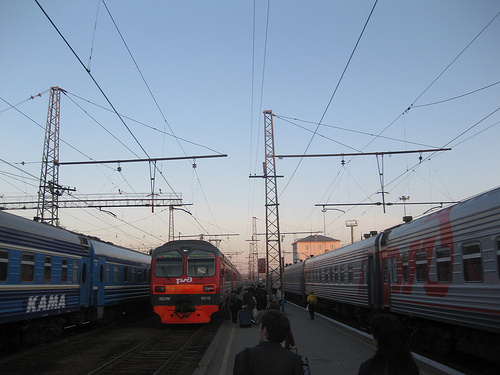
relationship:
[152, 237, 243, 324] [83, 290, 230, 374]
train on rail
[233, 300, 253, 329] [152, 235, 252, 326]
people waiting to board train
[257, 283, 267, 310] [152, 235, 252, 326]
people waiting to board train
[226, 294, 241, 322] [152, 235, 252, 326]
people waiting to board train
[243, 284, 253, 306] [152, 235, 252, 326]
people waiting to board train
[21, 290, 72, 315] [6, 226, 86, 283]
kama written on side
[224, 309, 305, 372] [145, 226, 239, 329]
man looking at train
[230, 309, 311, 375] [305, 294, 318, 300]
man wearing shirt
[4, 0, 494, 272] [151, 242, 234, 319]
sky above train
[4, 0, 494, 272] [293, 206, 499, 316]
sky above train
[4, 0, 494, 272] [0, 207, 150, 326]
sky above train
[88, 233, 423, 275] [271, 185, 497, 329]
sunset above train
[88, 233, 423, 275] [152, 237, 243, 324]
sunset above train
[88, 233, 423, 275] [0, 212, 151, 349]
sunset above train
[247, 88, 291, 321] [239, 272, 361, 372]
tower in walkway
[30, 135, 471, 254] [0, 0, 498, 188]
clouds in sky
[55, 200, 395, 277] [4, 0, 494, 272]
clouds in sky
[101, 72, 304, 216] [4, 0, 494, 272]
white clouds in sky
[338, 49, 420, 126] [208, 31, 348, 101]
white clouds in blue sky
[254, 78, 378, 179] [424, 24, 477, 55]
clouds in sky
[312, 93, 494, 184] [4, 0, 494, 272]
clouds in sky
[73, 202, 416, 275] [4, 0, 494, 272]
clouds in sky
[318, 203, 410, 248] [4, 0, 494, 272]
cloud in sky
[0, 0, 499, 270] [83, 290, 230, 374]
electric cables over rail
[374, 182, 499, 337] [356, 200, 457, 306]
passenger car with red letters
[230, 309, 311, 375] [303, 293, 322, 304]
man in a shirt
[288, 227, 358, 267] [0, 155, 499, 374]
building near railway station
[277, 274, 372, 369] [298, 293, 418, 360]
walkway between tracks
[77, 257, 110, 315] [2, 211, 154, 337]
doors for train cars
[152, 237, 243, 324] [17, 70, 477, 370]
train in railway station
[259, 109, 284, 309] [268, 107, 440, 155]
electric pole with cables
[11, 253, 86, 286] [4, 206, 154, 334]
windows of train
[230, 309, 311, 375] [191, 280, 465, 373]
man standing in platform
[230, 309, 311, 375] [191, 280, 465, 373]
man walking in platform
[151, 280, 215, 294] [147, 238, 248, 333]
headlight of train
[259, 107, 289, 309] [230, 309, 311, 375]
electric pole with man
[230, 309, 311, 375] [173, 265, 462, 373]
man standing in platform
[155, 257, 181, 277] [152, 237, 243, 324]
window of a train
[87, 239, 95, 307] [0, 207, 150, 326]
compartment of a train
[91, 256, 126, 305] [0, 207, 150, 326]
compartment of a train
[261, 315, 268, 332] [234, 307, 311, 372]
ear of a man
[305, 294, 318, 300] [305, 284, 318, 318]
shirt of a man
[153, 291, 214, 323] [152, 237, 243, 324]
engine on train